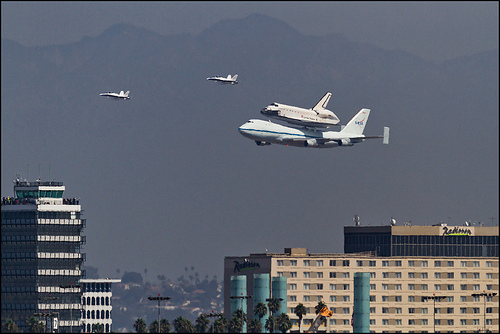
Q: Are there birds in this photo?
A: No, there are no birds.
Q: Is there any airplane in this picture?
A: Yes, there is an airplane.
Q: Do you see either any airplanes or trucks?
A: Yes, there is an airplane.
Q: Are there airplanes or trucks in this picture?
A: Yes, there is an airplane.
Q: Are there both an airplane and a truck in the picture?
A: No, there is an airplane but no trucks.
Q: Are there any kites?
A: No, there are no kites.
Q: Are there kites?
A: No, there are no kites.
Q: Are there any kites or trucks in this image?
A: No, there are no kites or trucks.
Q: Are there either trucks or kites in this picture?
A: No, there are no kites or trucks.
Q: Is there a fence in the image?
A: No, there are no fences.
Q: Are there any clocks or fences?
A: No, there are no fences or clocks.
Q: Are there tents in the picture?
A: No, there are no tents.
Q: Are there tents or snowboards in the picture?
A: No, there are no tents or snowboards.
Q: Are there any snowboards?
A: No, there are no snowboards.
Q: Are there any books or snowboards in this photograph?
A: No, there are no snowboards or books.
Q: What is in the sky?
A: The clouds are in the sky.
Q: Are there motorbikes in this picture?
A: No, there are no motorbikes.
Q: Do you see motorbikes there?
A: No, there are no motorbikes.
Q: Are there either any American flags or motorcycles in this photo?
A: No, there are no motorcycles or American flags.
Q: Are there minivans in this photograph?
A: No, there are no minivans.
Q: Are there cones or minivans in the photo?
A: No, there are no minivans or cones.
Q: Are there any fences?
A: No, there are no fences.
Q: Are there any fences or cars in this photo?
A: No, there are no fences or cars.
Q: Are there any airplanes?
A: Yes, there is an airplane.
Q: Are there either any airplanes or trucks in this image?
A: Yes, there is an airplane.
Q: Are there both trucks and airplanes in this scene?
A: No, there is an airplane but no trucks.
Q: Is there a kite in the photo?
A: No, there are no kites.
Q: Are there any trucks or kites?
A: No, there are no kites or trucks.